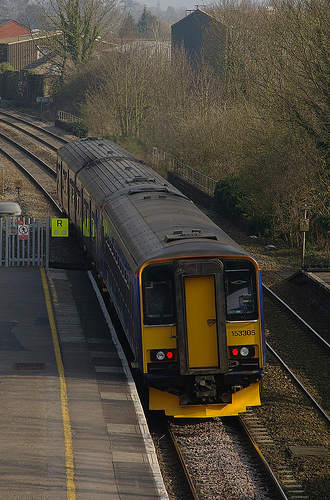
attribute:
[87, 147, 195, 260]
roof — black, blac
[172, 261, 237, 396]
door — closed, yellow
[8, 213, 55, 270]
gate — gray, closed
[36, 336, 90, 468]
line — yellow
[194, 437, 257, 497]
rocks — gray